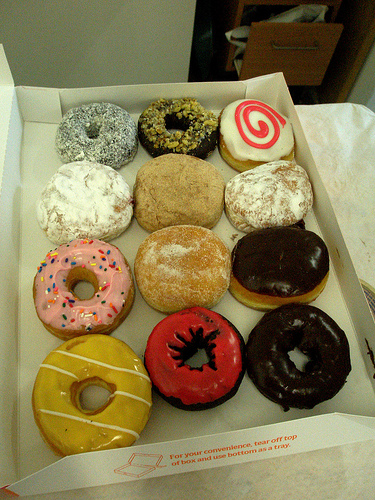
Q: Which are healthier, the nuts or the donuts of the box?
A: The nuts are healthier than the donuts.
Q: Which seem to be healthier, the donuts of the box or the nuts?
A: The nuts are healthier than the donuts.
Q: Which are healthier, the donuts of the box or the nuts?
A: The nuts are healthier than the donuts.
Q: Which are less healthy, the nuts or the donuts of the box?
A: The donuts are less healthy than the nuts.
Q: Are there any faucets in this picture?
A: No, there are no faucets.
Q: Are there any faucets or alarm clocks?
A: No, there are no faucets or alarm clocks.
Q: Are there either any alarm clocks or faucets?
A: No, there are no faucets or alarm clocks.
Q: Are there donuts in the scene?
A: Yes, there is a donut.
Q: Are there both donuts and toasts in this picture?
A: No, there is a donut but no toasts.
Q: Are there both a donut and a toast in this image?
A: No, there is a donut but no toasts.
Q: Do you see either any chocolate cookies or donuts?
A: Yes, there is a chocolate donut.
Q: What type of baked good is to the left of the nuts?
A: The food is a donut.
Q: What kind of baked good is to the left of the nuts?
A: The food is a donut.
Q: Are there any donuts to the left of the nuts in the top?
A: Yes, there is a donut to the left of the nuts.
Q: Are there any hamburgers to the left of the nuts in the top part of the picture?
A: No, there is a donut to the left of the nuts.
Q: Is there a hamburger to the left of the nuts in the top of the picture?
A: No, there is a donut to the left of the nuts.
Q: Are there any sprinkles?
A: Yes, there are sprinkles.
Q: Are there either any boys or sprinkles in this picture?
A: Yes, there are sprinkles.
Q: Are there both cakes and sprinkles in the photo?
A: No, there are sprinkles but no cakes.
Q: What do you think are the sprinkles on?
A: The sprinkles are on the donut.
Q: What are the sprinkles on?
A: The sprinkles are on the donut.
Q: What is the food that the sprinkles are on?
A: The food is a donut.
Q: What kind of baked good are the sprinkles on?
A: The sprinkles are on the doughnut.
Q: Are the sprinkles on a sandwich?
A: No, the sprinkles are on the doughnut.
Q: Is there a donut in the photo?
A: Yes, there is a donut.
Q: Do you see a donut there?
A: Yes, there is a donut.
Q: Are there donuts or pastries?
A: Yes, there is a donut.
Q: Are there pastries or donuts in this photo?
A: Yes, there is a donut.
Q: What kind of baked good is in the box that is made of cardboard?
A: The food is a donut.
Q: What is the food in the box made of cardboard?
A: The food is a donut.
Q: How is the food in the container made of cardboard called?
A: The food is a donut.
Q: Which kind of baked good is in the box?
A: The food is a donut.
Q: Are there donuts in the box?
A: Yes, there is a donut in the box.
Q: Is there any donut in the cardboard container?
A: Yes, there is a donut in the box.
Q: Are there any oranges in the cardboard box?
A: No, there is a donut in the box.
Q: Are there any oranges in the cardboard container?
A: No, there is a donut in the box.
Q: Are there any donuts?
A: Yes, there is a donut.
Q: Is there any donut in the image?
A: Yes, there is a donut.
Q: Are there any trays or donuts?
A: Yes, there is a donut.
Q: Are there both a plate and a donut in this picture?
A: No, there is a donut but no plates.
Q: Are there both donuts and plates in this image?
A: No, there is a donut but no plates.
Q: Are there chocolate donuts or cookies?
A: Yes, there is a chocolate donut.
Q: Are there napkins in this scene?
A: No, there are no napkins.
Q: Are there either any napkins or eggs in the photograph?
A: No, there are no napkins or eggs.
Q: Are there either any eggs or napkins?
A: No, there are no napkins or eggs.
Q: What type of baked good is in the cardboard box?
A: The food is a donut.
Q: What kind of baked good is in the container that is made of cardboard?
A: The food is a donut.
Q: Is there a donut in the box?
A: Yes, there is a donut in the box.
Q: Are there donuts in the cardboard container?
A: Yes, there is a donut in the box.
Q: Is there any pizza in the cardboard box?
A: No, there is a donut in the box.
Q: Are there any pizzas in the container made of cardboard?
A: No, there is a donut in the box.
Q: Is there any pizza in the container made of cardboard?
A: No, there is a donut in the box.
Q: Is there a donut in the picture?
A: Yes, there is a donut.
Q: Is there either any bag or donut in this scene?
A: Yes, there is a donut.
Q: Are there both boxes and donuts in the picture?
A: Yes, there are both a donut and a box.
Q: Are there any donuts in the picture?
A: Yes, there is a donut.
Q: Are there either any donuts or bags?
A: Yes, there is a donut.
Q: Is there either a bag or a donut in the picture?
A: Yes, there is a donut.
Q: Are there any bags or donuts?
A: Yes, there is a donut.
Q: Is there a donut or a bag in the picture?
A: Yes, there is a donut.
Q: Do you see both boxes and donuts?
A: Yes, there are both a donut and a box.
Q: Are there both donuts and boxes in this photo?
A: Yes, there are both a donut and a box.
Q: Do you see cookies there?
A: No, there are no cookies.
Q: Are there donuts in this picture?
A: Yes, there are donuts.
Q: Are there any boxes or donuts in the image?
A: Yes, there are donuts.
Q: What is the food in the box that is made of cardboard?
A: The food is donuts.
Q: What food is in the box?
A: The food is donuts.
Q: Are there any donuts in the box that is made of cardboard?
A: Yes, there are donuts in the box.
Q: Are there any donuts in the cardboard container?
A: Yes, there are donuts in the box.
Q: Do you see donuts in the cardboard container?
A: Yes, there are donuts in the box.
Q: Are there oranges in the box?
A: No, there are donuts in the box.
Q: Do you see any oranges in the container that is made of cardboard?
A: No, there are donuts in the box.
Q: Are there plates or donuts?
A: Yes, there is a donut.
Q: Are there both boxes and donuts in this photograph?
A: Yes, there are both a donut and a box.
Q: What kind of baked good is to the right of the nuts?
A: The food is a donut.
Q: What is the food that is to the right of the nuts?
A: The food is a donut.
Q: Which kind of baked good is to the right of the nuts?
A: The food is a donut.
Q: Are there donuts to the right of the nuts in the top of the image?
A: Yes, there is a donut to the right of the nuts.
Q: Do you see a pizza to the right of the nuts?
A: No, there is a donut to the right of the nuts.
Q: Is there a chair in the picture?
A: No, there are no chairs.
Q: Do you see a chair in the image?
A: No, there are no chairs.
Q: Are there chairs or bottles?
A: No, there are no chairs or bottles.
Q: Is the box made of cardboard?
A: Yes, the box is made of cardboard.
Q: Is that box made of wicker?
A: No, the box is made of cardboard.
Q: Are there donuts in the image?
A: Yes, there is a donut.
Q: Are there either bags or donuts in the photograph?
A: Yes, there is a donut.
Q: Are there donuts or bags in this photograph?
A: Yes, there is a donut.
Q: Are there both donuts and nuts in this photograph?
A: Yes, there are both a donut and nuts.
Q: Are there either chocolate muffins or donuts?
A: Yes, there is a chocolate donut.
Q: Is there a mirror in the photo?
A: No, there are no mirrors.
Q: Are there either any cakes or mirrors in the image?
A: No, there are no mirrors or cakes.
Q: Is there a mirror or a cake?
A: No, there are no mirrors or cakes.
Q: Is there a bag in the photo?
A: Yes, there is a bag.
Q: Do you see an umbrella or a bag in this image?
A: Yes, there is a bag.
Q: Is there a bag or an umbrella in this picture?
A: Yes, there is a bag.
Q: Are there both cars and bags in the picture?
A: No, there is a bag but no cars.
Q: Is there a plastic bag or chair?
A: Yes, there is a plastic bag.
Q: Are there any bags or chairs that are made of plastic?
A: Yes, the bag is made of plastic.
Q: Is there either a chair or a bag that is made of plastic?
A: Yes, the bag is made of plastic.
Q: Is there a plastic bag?
A: Yes, there is a bag that is made of plastic.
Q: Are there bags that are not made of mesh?
A: Yes, there is a bag that is made of plastic.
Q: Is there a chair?
A: No, there are no chairs.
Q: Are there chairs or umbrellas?
A: No, there are no chairs or umbrellas.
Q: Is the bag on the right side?
A: Yes, the bag is on the right of the image.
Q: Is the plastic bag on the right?
A: Yes, the bag is on the right of the image.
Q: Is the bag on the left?
A: No, the bag is on the right of the image.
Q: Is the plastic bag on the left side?
A: No, the bag is on the right of the image.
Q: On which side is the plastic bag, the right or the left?
A: The bag is on the right of the image.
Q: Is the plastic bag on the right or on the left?
A: The bag is on the right of the image.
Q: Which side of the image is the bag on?
A: The bag is on the right of the image.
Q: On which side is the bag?
A: The bag is on the right of the image.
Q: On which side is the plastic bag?
A: The bag is on the right of the image.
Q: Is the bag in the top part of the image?
A: Yes, the bag is in the top of the image.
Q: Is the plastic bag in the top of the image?
A: Yes, the bag is in the top of the image.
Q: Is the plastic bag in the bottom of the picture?
A: No, the bag is in the top of the image.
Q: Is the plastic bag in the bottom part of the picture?
A: No, the bag is in the top of the image.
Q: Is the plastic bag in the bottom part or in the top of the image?
A: The bag is in the top of the image.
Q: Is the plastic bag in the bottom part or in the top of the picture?
A: The bag is in the top of the image.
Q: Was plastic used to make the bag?
A: Yes, the bag is made of plastic.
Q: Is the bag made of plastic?
A: Yes, the bag is made of plastic.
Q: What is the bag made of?
A: The bag is made of plastic.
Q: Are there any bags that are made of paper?
A: No, there is a bag but it is made of plastic.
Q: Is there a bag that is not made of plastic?
A: No, there is a bag but it is made of plastic.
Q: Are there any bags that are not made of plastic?
A: No, there is a bag but it is made of plastic.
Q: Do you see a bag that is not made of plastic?
A: No, there is a bag but it is made of plastic.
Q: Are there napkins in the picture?
A: No, there are no napkins.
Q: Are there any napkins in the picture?
A: No, there are no napkins.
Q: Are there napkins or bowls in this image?
A: No, there are no napkins or bowls.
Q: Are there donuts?
A: Yes, there is a donut.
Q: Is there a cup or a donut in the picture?
A: Yes, there is a donut.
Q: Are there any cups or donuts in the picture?
A: Yes, there is a donut.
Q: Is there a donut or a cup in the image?
A: Yes, there is a donut.